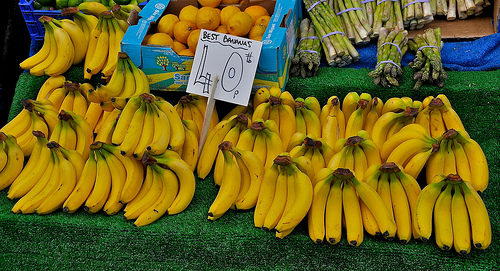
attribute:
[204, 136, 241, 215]
banana — yellow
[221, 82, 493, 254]
bananas — yellow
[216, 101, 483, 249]
bananas — yellow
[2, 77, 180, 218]
bananas — yellow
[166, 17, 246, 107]
sign — white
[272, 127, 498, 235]
bananas — yelloe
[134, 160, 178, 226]
banana — yellow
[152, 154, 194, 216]
banana — yellow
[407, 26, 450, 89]
asparagus — green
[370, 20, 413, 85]
asparagus — green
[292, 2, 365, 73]
asparagus — green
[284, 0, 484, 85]
asparagus — green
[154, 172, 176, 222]
banana — yellow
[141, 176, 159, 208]
banana — yellow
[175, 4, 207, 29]
oranges — orange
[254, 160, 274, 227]
banana — yellow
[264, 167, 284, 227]
banana — yellow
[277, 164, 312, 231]
banana — yellow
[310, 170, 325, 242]
banana — yellow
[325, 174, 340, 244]
banana — yellow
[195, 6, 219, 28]
fruit — orange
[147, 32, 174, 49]
fruit — orange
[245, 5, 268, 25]
fruit — orange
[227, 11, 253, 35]
fruit — orange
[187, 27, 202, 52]
fruit — orange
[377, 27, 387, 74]
veggie — green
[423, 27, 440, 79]
veggie — green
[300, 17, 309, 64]
veggie — green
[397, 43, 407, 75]
veggie — green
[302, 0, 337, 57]
veggie — green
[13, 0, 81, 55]
milk crate — blue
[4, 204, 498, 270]
grass — green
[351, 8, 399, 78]
asparagus — green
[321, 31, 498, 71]
tarp — blue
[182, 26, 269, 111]
sign — white, black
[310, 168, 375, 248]
banana — yellow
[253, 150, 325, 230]
banana — yellow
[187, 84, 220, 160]
wooden stick — wood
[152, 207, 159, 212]
spot — brown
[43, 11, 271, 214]
fruits — yellow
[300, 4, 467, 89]
veggies — green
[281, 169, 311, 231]
banana — yellow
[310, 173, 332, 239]
banana — yellow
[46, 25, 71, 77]
banana — yellow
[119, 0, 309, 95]
box —  blue cardboard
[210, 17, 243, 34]
oranges — orange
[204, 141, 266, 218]
banana bundle — ripe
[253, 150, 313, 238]
banana bundle — ripe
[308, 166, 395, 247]
banana bundle — ripe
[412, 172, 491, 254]
banana bundle — ripe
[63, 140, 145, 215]
banana bundle — ripe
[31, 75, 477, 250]
bananas — yellow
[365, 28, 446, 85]
vegetables — green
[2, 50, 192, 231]
bananas — yellow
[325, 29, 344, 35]
bands — blue 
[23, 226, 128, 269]
fuzzy material — green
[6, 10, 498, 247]
table — full